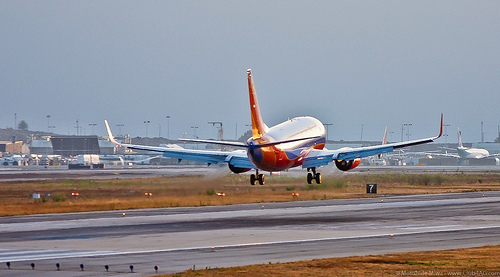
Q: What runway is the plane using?
A: Seven.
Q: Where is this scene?
A: At an airport.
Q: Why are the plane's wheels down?
A: For taxiing before takeoff.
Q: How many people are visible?
A: None.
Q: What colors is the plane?
A: Silver, blue, red, and yellow.